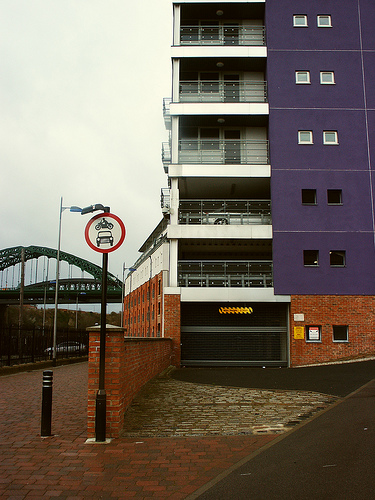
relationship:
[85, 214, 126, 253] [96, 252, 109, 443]
sign on top of pole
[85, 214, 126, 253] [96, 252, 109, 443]
sign in on top of pole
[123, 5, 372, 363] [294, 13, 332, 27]
building has windows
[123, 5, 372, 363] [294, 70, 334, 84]
building has windows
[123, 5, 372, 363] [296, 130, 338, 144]
building has windows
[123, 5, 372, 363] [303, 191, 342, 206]
building has windows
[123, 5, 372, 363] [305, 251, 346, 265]
building has windows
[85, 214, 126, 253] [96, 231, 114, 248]
sign showing car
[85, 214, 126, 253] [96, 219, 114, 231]
sign showing motorcycle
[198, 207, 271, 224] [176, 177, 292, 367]
car parked in garage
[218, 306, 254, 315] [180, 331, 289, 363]
sign on top of door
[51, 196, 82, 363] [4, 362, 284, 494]
light on top of ground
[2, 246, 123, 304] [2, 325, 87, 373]
bridge behind garage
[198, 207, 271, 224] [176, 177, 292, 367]
car inside garage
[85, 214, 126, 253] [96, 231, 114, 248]
sign has car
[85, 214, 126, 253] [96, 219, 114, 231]
sign has motorcycle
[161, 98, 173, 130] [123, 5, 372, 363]
balcony on side of building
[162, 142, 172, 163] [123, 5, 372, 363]
balcony on side of building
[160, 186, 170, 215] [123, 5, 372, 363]
balcony on side of building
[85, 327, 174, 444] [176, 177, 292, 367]
wall leading to garage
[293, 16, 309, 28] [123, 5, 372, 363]
window on side of building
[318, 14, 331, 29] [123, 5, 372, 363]
window on side of building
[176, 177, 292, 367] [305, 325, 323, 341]
garage has window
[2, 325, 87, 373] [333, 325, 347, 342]
garage has window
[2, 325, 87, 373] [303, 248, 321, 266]
garage has window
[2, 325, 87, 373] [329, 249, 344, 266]
garage has window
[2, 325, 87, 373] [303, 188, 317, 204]
garage has window